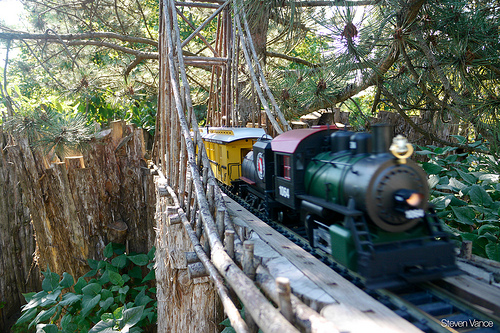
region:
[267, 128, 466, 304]
A black red and green train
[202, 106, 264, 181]
A yellow train car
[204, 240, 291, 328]
A wooden pole fance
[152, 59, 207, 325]
A wooden pole fance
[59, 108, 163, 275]
A wooden pole fance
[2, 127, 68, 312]
A wooden pole fance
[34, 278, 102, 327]
A green healhy vegetation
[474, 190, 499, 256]
A green healhy vegetation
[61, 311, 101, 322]
White and yellow sign on top of train.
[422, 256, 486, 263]
White and yellow sign on top of train.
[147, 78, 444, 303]
a miniature train on the bridge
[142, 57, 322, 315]
bridge made of wood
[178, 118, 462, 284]
Train moving on the bridge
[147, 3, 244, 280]
Bridge strut support near the train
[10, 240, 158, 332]
Green leaves below the bridge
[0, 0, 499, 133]
Forest of trees in the back ground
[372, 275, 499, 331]
Train tracks in fron of the train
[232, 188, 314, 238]
Train wheels of the train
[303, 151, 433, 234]
Engine of the train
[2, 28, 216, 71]
Brown branch of the tree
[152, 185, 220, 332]
Brown wood ground support of the bridge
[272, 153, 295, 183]
Window of the train